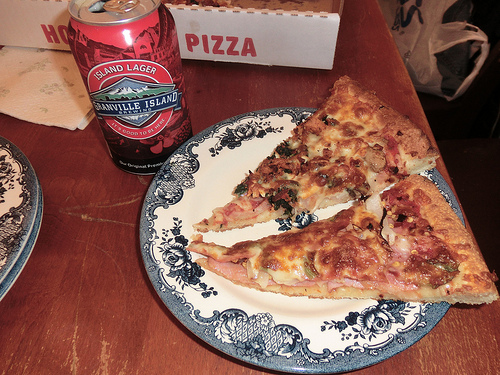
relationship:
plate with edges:
[126, 84, 457, 374] [135, 96, 484, 367]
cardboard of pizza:
[1, 0, 342, 69] [170, 3, 352, 83]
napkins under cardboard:
[0, 52, 92, 130] [1, 0, 346, 72]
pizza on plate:
[193, 72, 444, 228] [132, 103, 462, 370]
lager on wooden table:
[65, 0, 196, 178] [0, 0, 500, 375]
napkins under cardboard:
[0, 52, 99, 133] [1, 0, 346, 72]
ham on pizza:
[249, 179, 269, 209] [183, 52, 498, 333]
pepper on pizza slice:
[301, 252, 320, 278] [175, 171, 500, 309]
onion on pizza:
[407, 251, 471, 294] [362, 195, 421, 251]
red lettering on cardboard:
[186, 19, 334, 77] [1, 0, 346, 72]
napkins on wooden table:
[0, 52, 99, 133] [0, 0, 500, 375]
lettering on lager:
[82, 59, 158, 82] [65, 0, 196, 178]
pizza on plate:
[190, 72, 445, 236] [129, 132, 194, 289]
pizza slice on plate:
[175, 171, 497, 309] [1, 129, 46, 301]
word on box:
[182, 31, 257, 58] [0, 0, 346, 70]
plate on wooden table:
[0, 134, 40, 288] [0, 0, 500, 375]